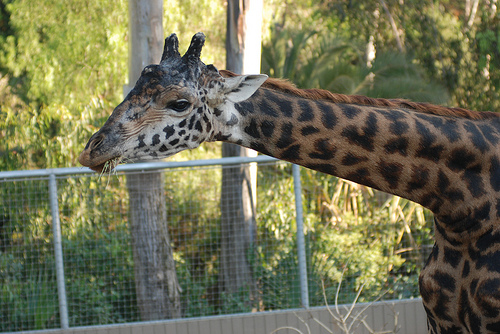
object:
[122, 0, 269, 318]
tree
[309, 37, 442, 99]
foliage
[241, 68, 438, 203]
neck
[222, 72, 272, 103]
ear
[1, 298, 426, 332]
fence base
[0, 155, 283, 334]
grass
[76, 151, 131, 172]
mouth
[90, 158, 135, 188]
straw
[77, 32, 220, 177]
head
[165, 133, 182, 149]
brown spot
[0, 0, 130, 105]
leaves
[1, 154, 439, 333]
fence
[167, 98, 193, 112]
eye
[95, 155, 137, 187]
hay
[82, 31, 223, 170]
trunk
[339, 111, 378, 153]
spot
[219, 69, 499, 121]
main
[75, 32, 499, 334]
giraffe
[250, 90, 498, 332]
brown spot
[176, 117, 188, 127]
spt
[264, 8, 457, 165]
tree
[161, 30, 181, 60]
horn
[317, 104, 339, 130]
spot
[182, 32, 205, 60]
horn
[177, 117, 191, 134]
spot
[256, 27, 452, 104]
palm frond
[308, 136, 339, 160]
spot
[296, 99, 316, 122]
spot